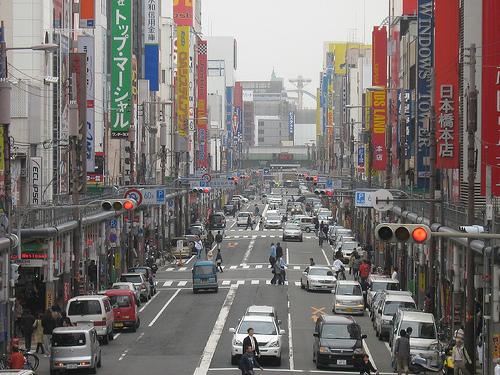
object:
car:
[300, 265, 338, 292]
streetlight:
[364, 82, 407, 96]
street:
[204, 300, 290, 373]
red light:
[412, 226, 427, 244]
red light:
[122, 201, 134, 211]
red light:
[325, 190, 332, 196]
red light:
[313, 176, 319, 181]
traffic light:
[312, 188, 333, 196]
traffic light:
[95, 197, 138, 212]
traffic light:
[192, 186, 212, 194]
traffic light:
[226, 176, 241, 182]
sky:
[202, 2, 280, 34]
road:
[171, 295, 230, 334]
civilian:
[235, 345, 266, 375]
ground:
[296, 243, 317, 256]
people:
[267, 239, 285, 268]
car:
[126, 267, 160, 296]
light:
[371, 221, 432, 245]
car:
[95, 288, 142, 334]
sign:
[105, 0, 134, 133]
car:
[388, 309, 441, 366]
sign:
[17, 251, 48, 260]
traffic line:
[241, 235, 259, 264]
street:
[243, 255, 367, 280]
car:
[330, 278, 368, 315]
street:
[217, 182, 329, 219]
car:
[226, 313, 285, 365]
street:
[125, 280, 228, 320]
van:
[370, 293, 416, 341]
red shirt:
[7, 352, 23, 369]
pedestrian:
[5, 344, 30, 369]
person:
[239, 327, 262, 358]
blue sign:
[416, 0, 433, 189]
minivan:
[190, 260, 219, 293]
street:
[287, 271, 366, 318]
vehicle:
[49, 324, 108, 375]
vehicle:
[282, 223, 305, 243]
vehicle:
[60, 294, 116, 346]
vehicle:
[364, 275, 402, 312]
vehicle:
[264, 213, 284, 229]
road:
[110, 334, 194, 374]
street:
[204, 229, 244, 254]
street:
[152, 254, 216, 280]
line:
[203, 325, 223, 359]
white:
[264, 31, 299, 56]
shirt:
[267, 245, 277, 261]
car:
[238, 305, 283, 325]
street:
[292, 315, 395, 373]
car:
[310, 313, 372, 370]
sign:
[431, 1, 464, 169]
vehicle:
[101, 287, 141, 331]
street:
[231, 278, 288, 308]